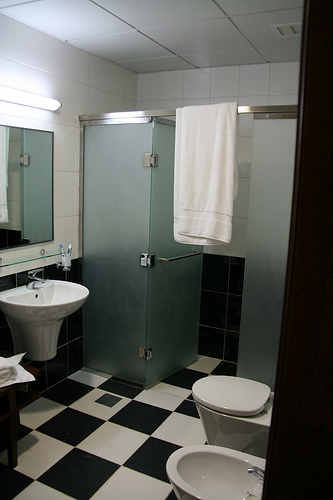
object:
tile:
[79, 423, 149, 468]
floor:
[1, 357, 242, 499]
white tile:
[0, 430, 73, 477]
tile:
[132, 382, 192, 411]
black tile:
[36, 407, 107, 450]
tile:
[38, 450, 120, 499]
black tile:
[109, 401, 171, 435]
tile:
[44, 381, 95, 408]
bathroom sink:
[1, 279, 89, 364]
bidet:
[167, 446, 266, 499]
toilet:
[191, 374, 273, 456]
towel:
[171, 105, 238, 250]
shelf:
[0, 243, 69, 270]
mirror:
[0, 126, 54, 249]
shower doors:
[150, 125, 204, 384]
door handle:
[157, 251, 204, 267]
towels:
[2, 354, 27, 387]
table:
[0, 370, 39, 472]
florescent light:
[4, 89, 60, 113]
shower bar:
[79, 103, 298, 115]